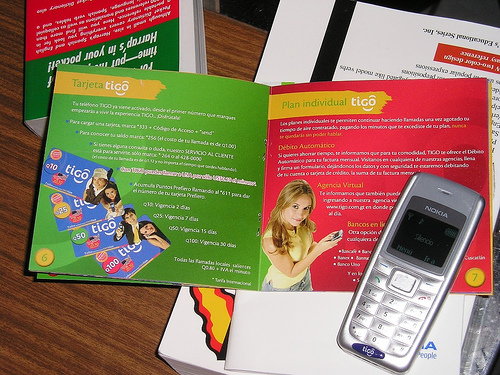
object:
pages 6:
[33, 247, 55, 267]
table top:
[0, 0, 499, 373]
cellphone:
[336, 172, 486, 374]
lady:
[259, 178, 342, 291]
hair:
[261, 178, 317, 254]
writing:
[184, 237, 236, 247]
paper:
[27, 63, 269, 291]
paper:
[258, 77, 493, 292]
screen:
[391, 207, 463, 268]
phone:
[336, 171, 488, 374]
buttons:
[390, 271, 416, 292]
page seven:
[463, 267, 486, 287]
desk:
[0, 0, 499, 373]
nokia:
[424, 204, 449, 220]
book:
[29, 63, 494, 293]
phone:
[331, 228, 343, 238]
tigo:
[105, 79, 130, 91]